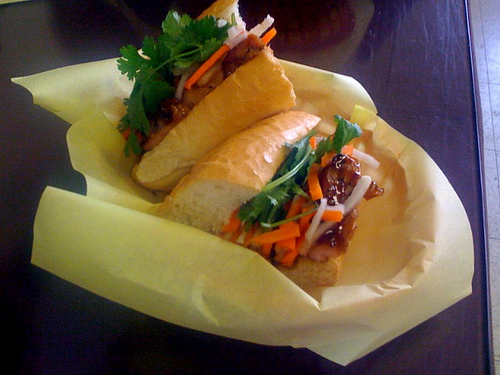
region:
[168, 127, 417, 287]
Food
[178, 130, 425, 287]
one half of a sandwich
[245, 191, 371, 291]
Carrots on a sandwich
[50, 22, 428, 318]
A cut sandwich on paper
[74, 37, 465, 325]
A cut sandwich on paper in a bowl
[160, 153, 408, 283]
Vegetables on a sandwich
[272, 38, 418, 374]
A sandwich in a bowl on a table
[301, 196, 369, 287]
Meat in a sandwich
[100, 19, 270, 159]
Parsley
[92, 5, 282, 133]
Parsley on a sandwich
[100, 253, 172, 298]
this is a paper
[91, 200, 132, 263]
the paper is white in color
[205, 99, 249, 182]
this is some bread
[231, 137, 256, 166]
the bread's top is brown in color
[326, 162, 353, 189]
this is some meat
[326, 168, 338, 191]
the meat is oily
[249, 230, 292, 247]
there are some carrots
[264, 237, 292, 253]
the carrots are orange in color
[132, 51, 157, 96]
these are some spices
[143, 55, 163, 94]
the leaves are green in color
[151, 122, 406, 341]
half a slice of sandwich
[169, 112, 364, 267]
v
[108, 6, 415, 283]
A sandwich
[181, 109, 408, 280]
Half of a sandwich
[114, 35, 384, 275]
two halves of a sandwich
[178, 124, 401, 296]
A sandwich on a roll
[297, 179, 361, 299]
Meat on a sandwich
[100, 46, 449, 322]
A sandwich on paper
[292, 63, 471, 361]
Paper in a bowl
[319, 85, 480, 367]
A bowl on a blue table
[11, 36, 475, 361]
the sandwich is on a yellow napkin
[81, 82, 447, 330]
a plate is underneath the towel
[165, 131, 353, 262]
the food is between two pieces of bread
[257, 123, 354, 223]
the meal contains parsley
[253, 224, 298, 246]
sliced carrots are in the sandwich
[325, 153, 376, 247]
the meat is moist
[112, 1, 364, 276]
the sandwich is cut in half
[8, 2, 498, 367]
the meal is on a dark table cloth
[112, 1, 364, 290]
half a sandwich is behind the other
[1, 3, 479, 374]
the tablecloth is dark in color